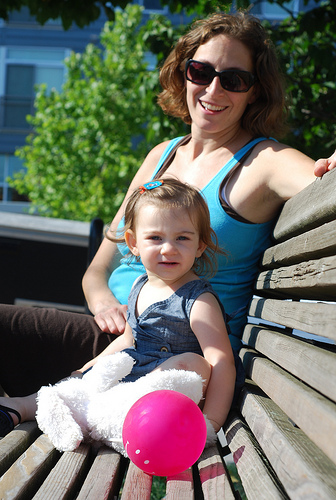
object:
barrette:
[138, 179, 164, 192]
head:
[179, 15, 260, 133]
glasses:
[184, 57, 256, 93]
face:
[185, 32, 253, 134]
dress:
[81, 273, 227, 383]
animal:
[33, 351, 216, 461]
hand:
[91, 301, 129, 334]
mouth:
[198, 98, 228, 115]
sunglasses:
[182, 56, 259, 94]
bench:
[0, 167, 335, 498]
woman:
[0, 9, 335, 398]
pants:
[0, 303, 121, 397]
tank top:
[107, 136, 279, 351]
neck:
[189, 123, 241, 144]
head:
[123, 179, 210, 281]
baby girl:
[0, 176, 236, 448]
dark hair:
[157, 14, 290, 137]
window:
[1, 54, 35, 137]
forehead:
[190, 32, 253, 71]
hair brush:
[185, 32, 198, 49]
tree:
[4, 3, 335, 226]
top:
[133, 178, 195, 212]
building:
[0, 0, 334, 215]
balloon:
[121, 387, 208, 478]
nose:
[204, 76, 224, 97]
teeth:
[198, 101, 227, 111]